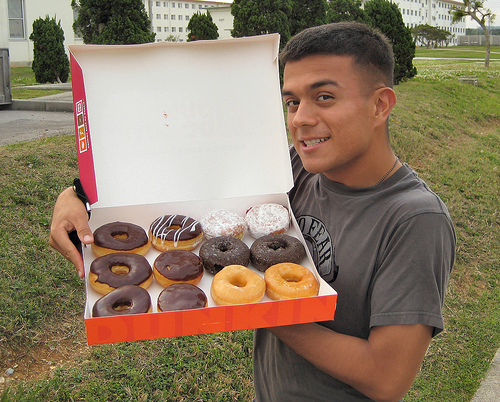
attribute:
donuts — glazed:
[186, 263, 330, 310]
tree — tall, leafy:
[445, 0, 495, 65]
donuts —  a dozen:
[92, 190, 273, 300]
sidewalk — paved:
[470, 348, 499, 400]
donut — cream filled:
[152, 245, 207, 284]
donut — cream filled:
[155, 280, 207, 311]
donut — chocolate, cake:
[198, 238, 250, 275]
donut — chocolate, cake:
[250, 235, 307, 272]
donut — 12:
[94, 222, 145, 259]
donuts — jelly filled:
[196, 198, 293, 240]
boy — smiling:
[273, 30, 455, 392]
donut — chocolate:
[93, 220, 147, 251]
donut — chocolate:
[91, 251, 151, 288]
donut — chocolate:
[91, 282, 148, 317]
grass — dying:
[383, 44, 498, 393]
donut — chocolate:
[200, 235, 248, 272]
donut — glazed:
[214, 265, 274, 317]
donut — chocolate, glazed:
[92, 214, 155, 269]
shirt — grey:
[261, 177, 451, 399]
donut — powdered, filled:
[199, 208, 246, 238]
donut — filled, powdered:
[244, 200, 290, 235]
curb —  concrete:
[8, 98, 74, 110]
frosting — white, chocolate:
[150, 212, 203, 241]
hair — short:
[272, 19, 394, 93]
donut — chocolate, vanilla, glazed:
[151, 209, 202, 254]